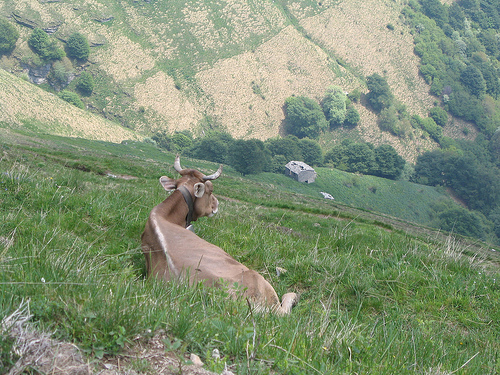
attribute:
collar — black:
[169, 177, 199, 221]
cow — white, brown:
[140, 149, 299, 320]